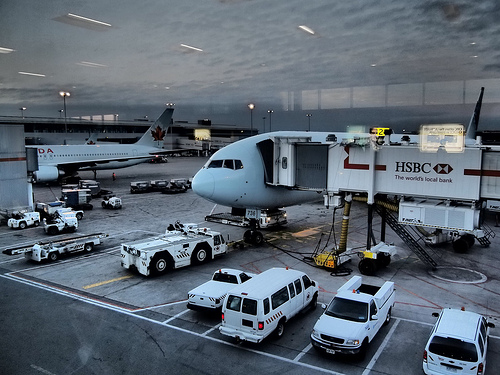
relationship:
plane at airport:
[194, 88, 493, 205] [9, 115, 341, 371]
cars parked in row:
[422, 308, 491, 374] [29, 270, 389, 344]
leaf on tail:
[151, 125, 166, 145] [120, 97, 185, 174]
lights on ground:
[243, 96, 260, 126] [0, 155, 499, 374]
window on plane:
[208, 156, 228, 174] [168, 115, 452, 257]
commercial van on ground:
[221, 267, 318, 343] [82, 287, 270, 354]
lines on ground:
[280, 346, 305, 374] [41, 280, 203, 351]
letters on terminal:
[391, 157, 429, 174] [329, 137, 499, 200]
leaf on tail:
[143, 122, 174, 147] [132, 96, 170, 144]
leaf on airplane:
[151, 125, 166, 145] [20, 129, 150, 175]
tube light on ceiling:
[174, 39, 209, 59] [5, 3, 496, 103]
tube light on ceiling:
[294, 19, 317, 41] [5, 3, 496, 103]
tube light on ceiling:
[62, 8, 117, 35] [5, 3, 496, 103]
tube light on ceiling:
[15, 63, 48, 82] [5, 3, 496, 103]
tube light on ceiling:
[0, 44, 15, 59] [5, 3, 496, 103]